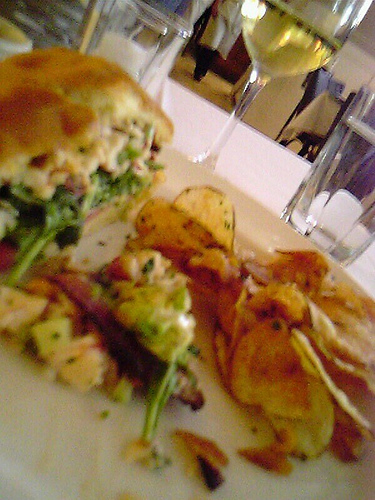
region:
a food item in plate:
[13, 64, 172, 225]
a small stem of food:
[144, 380, 196, 458]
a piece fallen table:
[137, 392, 264, 493]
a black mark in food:
[62, 350, 94, 373]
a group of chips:
[172, 189, 363, 445]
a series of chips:
[155, 190, 359, 337]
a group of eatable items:
[29, 118, 361, 420]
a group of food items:
[18, 51, 360, 331]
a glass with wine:
[224, 0, 365, 129]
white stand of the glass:
[214, 63, 270, 149]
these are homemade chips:
[189, 246, 333, 459]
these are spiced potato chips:
[171, 210, 352, 490]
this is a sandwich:
[33, 186, 111, 264]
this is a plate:
[88, 465, 91, 470]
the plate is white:
[52, 458, 96, 486]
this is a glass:
[274, 181, 338, 213]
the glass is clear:
[336, 179, 362, 227]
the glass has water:
[272, 144, 370, 261]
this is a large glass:
[190, 80, 269, 147]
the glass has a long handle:
[218, 101, 233, 133]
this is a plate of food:
[156, 288, 316, 471]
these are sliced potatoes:
[153, 221, 283, 360]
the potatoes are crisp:
[166, 295, 329, 367]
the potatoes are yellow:
[245, 305, 287, 399]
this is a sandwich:
[33, 229, 172, 372]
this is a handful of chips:
[164, 270, 369, 442]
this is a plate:
[21, 429, 93, 483]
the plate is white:
[82, 395, 116, 455]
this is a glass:
[295, 148, 363, 251]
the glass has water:
[306, 160, 337, 246]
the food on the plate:
[17, 41, 364, 402]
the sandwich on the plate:
[10, 53, 166, 249]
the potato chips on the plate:
[169, 188, 370, 443]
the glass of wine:
[183, 0, 359, 166]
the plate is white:
[8, 143, 373, 495]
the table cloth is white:
[147, 79, 365, 238]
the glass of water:
[280, 82, 373, 260]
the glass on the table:
[85, 0, 181, 86]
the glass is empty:
[55, 6, 190, 91]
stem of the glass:
[197, 70, 268, 165]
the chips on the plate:
[158, 191, 372, 446]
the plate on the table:
[1, 149, 365, 496]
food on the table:
[2, 39, 374, 499]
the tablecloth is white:
[243, 129, 292, 196]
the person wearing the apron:
[189, 7, 229, 96]